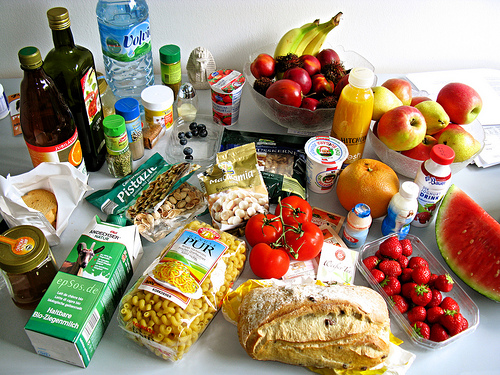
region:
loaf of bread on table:
[239, 284, 397, 370]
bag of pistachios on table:
[85, 150, 218, 243]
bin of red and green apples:
[371, 76, 486, 193]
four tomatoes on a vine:
[248, 198, 325, 288]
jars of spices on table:
[92, 86, 152, 185]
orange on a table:
[341, 152, 396, 217]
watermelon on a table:
[438, 175, 498, 329]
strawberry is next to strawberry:
[378, 235, 401, 258]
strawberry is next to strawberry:
[364, 253, 380, 266]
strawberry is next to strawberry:
[400, 237, 413, 254]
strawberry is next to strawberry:
[370, 268, 385, 282]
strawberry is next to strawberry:
[377, 258, 402, 275]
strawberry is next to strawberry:
[381, 275, 400, 294]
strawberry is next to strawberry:
[408, 283, 434, 306]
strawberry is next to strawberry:
[392, 293, 407, 314]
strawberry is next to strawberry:
[414, 318, 429, 338]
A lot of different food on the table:
[4, 1, 497, 372]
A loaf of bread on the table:
[241, 283, 390, 369]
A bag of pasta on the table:
[117, 215, 249, 361]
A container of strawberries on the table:
[367, 216, 483, 346]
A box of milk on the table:
[24, 212, 144, 370]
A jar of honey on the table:
[2, 219, 56, 318]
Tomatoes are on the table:
[241, 190, 329, 279]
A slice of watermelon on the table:
[427, 180, 497, 305]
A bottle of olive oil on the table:
[41, 5, 114, 179]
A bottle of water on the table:
[94, 0, 158, 100]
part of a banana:
[277, 18, 318, 50]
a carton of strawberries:
[357, 232, 479, 347]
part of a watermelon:
[435, 185, 499, 302]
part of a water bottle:
[87, 0, 157, 92]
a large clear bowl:
[233, 44, 375, 128]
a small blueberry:
[181, 145, 193, 154]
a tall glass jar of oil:
[31, 8, 112, 169]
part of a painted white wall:
[172, 2, 268, 40]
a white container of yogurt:
[303, 135, 343, 195]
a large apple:
[438, 78, 482, 120]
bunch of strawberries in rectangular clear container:
[359, 228, 481, 355]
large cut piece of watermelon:
[430, 179, 499, 308]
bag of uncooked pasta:
[119, 212, 244, 363]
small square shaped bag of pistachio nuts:
[86, 147, 211, 237]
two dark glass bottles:
[9, 4, 109, 192]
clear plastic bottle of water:
[89, 0, 155, 97]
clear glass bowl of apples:
[373, 66, 489, 175]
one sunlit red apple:
[438, 77, 487, 124]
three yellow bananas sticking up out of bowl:
[271, 8, 346, 52]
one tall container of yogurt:
[205, 64, 247, 128]